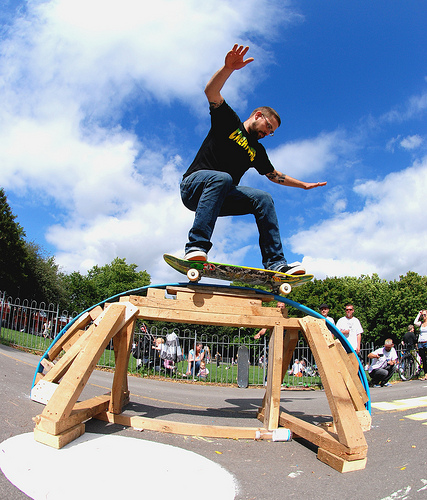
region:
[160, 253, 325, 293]
a colorful skateboard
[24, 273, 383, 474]
a wooden skateboard ramp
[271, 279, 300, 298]
wheels on a skateboard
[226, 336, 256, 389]
a black skateboard leaning on a fence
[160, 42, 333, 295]
a guy riding a skateboard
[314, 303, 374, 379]
two guys watching a guy skate board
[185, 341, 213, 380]
a mother and a child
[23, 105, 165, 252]
white fluffy clouds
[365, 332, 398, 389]
a man videoing a skateboarder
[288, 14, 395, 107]
a piece of blue sky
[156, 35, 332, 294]
Man skateboarding on half circle.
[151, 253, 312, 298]
Multi colored skateboard with white wheels.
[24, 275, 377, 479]
Wooden and plastic half circle.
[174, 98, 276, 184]
Black shirt with yellow writing.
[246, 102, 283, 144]
Skateboarding man wearing glasses.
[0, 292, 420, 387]
Metal fence in background.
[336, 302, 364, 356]
Man in white shirt.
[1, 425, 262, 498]
White circle painted on ground.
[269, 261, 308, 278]
Black and white shoe.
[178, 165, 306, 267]
Blue jeans on man.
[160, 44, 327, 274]
A person riding a skateboard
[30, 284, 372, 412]
a blue rail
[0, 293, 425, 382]
A metal fence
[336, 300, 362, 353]
A man in a white shirt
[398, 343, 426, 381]
A bicycle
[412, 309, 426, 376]
A woman in a white shirt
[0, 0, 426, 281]
A clear blue sky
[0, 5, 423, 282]
some clouds in the sky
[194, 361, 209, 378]
A baby sitting on the ground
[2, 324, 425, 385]
A grassy field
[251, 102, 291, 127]
Man has short hair.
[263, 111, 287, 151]
Glasses on man's face.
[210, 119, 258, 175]
Man wearing black shirt.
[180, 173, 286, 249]
Man wearing blue jeans.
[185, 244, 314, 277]
Man wearing black and white shoes.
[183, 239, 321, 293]
Man standing on skateboard.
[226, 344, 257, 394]
Black skateboard leaning against fence.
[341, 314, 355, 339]
Person wearing white shirt.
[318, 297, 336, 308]
Black hat on person's head.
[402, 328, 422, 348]
Person wearing black shirt.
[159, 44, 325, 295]
a man on a skateboard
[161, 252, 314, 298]
a multi colored skateboard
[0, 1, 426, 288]
a cloudy blue sky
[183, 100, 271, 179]
a black printed t-shirt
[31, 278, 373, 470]
a wooded skate ramp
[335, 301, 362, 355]
a man watching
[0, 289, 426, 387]
a long metal fence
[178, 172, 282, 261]
a pair of men's blue jeans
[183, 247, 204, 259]
a black and white shoe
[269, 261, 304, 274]
a black and white shoe